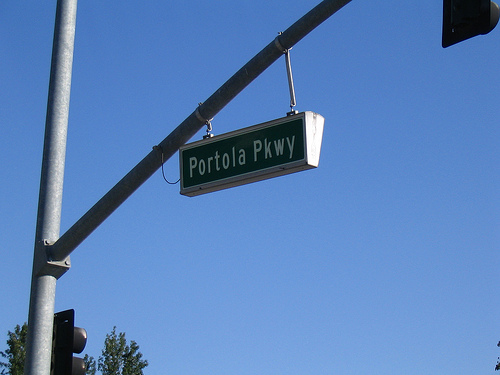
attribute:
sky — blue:
[208, 196, 475, 370]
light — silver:
[50, 305, 97, 373]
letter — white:
[232, 144, 248, 169]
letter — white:
[184, 146, 204, 184]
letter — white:
[250, 132, 262, 162]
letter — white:
[197, 148, 211, 177]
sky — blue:
[2, 1, 498, 370]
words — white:
[179, 128, 299, 188]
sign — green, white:
[170, 104, 335, 205]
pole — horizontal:
[62, 15, 352, 271]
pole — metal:
[24, 3, 78, 373]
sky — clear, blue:
[222, 226, 412, 329]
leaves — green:
[115, 341, 133, 355]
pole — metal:
[22, 4, 65, 373]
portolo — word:
[182, 139, 252, 188]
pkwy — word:
[248, 126, 298, 162]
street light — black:
[48, 299, 95, 371]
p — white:
[182, 146, 198, 180]